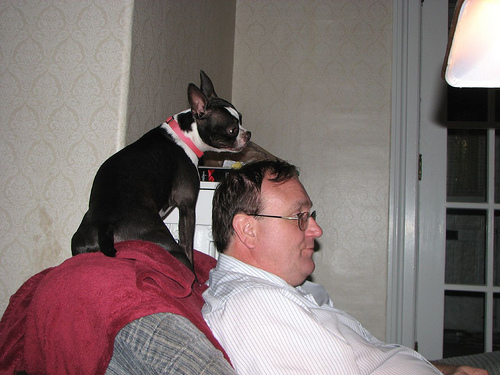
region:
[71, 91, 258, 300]
dog has black fur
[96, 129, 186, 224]
dog has black fur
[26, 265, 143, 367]
blanket is dark red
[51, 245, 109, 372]
blanket is dark red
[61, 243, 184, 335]
blanket is dark red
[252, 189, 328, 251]
Glasses on man's face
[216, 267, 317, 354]
Man wearing white shirt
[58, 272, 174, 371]
Red blanket over back of chair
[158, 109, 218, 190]
Dog wearing pink collar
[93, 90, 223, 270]
Dog is black and white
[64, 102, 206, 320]
Dog is sitting on the back of chair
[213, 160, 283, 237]
Man has dark hair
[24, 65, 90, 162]
Wall is printed and white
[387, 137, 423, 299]
Door frame is white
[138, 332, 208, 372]
Chair is grayish blue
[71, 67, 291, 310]
a small dog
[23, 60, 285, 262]
a black and white small dog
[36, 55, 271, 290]
a small dog wearing a collar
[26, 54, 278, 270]
a small dog wearing a pink collar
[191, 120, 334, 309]
a man wearing glasses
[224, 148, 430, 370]
a man wearing a white shirt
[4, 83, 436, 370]
a dog sitting on the back of a chair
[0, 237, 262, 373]
a red blanket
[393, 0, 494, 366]
a white door frame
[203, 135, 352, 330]
a man with brown hair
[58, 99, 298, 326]
dog is black and white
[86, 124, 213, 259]
dog is black and white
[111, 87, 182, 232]
dog is black and white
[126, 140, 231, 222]
dog is black and white